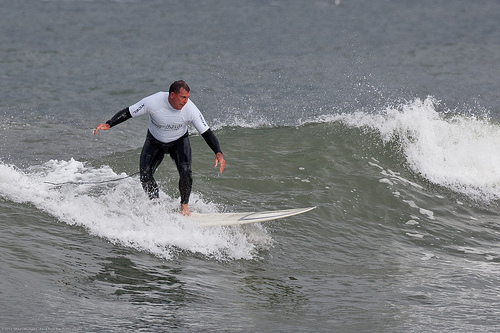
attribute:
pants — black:
[141, 131, 192, 203]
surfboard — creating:
[154, 209, 316, 224]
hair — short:
[167, 76, 190, 93]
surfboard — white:
[179, 205, 317, 225]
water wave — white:
[245, 91, 496, 214]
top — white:
[124, 91, 210, 147]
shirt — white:
[102, 89, 231, 158]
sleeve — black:
[191, 114, 222, 156]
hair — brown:
[169, 78, 191, 94]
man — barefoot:
[99, 79, 240, 192]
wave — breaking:
[326, 90, 496, 202]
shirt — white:
[130, 92, 210, 145]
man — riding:
[100, 76, 262, 233]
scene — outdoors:
[2, 5, 498, 328]